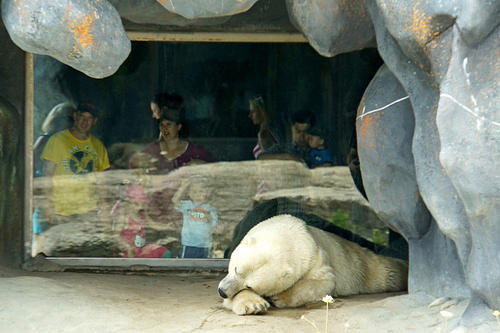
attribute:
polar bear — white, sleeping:
[215, 211, 406, 316]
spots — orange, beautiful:
[66, 11, 110, 48]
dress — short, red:
[112, 197, 164, 259]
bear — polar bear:
[216, 211, 410, 316]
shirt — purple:
[123, 134, 219, 175]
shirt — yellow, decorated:
[40, 128, 110, 213]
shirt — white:
[168, 166, 225, 253]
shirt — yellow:
[40, 131, 108, 221]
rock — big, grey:
[359, 60, 436, 241]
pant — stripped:
[171, 240, 217, 257]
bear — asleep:
[222, 215, 414, 330]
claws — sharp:
[217, 289, 271, 318]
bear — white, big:
[207, 209, 405, 314]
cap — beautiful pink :
[120, 179, 147, 205]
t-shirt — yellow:
[42, 127, 110, 217]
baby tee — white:
[176, 200, 219, 249]